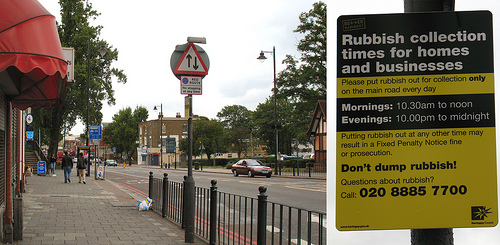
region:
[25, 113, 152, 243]
a sidewalk with people on it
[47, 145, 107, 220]
people walking on a sidewalk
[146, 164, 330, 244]
a black fence near the street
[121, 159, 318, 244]
a black fence near the sidewalk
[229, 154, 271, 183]
a car in the street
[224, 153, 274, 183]
a parked car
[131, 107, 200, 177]
a brown building in the distance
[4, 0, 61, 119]
a red awning on a building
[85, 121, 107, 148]
a blue sign on the sidewalk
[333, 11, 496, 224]
a black and yellow sign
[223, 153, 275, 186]
Red car on road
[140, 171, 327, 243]
Black iron fence near curb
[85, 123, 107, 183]
Blue sign on sidewalk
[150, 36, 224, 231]
Sign next to fence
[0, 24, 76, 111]
Red awing on building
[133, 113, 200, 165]
Brown building in background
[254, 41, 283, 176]
Black lamp post near curb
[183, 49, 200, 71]
Black arrow on sign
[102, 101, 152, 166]
Tree near brown building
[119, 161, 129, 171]
Yellow fire hydrant in background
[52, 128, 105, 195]
two people walking at the sidewalk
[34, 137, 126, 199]
two people walking at the sidewalk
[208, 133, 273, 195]
a red car at the street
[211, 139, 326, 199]
a red car at the street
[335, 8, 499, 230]
Black, white, and yellow sign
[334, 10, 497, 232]
Sign stating rubbish collection times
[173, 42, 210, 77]
Red and white triangular sign with black arrows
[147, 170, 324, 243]
Black rail fence along curb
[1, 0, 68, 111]
Red fabric awning above entrance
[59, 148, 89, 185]
Two people walking on sidewalk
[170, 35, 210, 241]
Post with several signs and traffic camera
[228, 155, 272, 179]
Small red car in street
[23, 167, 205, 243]
Sidewalk made of interlocking bricks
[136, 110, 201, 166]
Large brick building in background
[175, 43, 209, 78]
Sign shaped like a triangle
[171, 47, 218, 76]
The sign has two arrows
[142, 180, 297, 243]
Fence along the sidewalk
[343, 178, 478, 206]
Number to call for trash collection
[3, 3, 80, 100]
Red awning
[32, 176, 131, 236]
Sidewalk made of brick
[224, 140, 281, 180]
Red car parked along side of road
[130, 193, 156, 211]
Small bag leaning against the fence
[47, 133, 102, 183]
Two people walking down the sidewalk